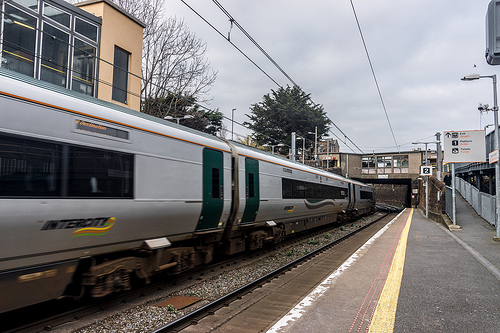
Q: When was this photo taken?
A: Early morning.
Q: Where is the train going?
A: To pick up/drop off more passengers.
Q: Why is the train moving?
A: It has to make more stops.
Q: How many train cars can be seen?
A: 3.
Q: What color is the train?
A: Grey and green.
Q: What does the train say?
A: Interotti.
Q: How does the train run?
A: Electricity.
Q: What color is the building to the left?
A: Tan.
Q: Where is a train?
A: On train tracks.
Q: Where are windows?
A: On the train.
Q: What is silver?
A: The train.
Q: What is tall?
A: Trees.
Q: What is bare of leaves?
A: A tree.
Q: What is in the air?
A: Telephone wires.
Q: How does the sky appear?
A: Cloudy.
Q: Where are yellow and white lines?
A: On the ground.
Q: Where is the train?
A: On train tracks.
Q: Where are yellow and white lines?
A: On the ground.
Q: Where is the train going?
A: Under the tunnel.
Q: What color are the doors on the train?
A: Green.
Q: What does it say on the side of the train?
A: Intercity.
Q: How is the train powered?
A: Electricity.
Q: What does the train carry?
A: People.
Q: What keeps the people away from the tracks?
A: A yellow line.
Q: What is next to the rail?
A: Gravel.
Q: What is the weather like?
A: Cloudy.